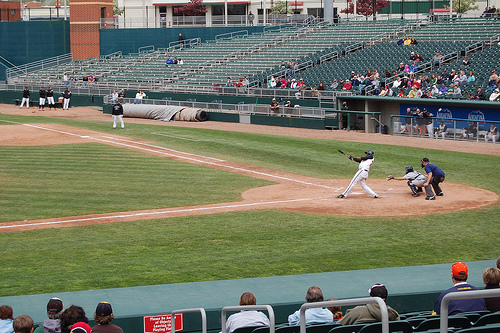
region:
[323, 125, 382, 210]
a man swinging a baseball bat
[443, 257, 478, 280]
a red cap on a head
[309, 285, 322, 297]
a bald spot on a head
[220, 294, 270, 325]
a man wearing a light blue shirt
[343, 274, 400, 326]
a man wearing a gray hoodie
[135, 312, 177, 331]
a red and white safety sign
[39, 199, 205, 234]
a white chalk line in the dirt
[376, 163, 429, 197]
a catcher reaching for the ball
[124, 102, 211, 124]
a long rolls of astro turf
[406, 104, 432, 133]
coaches watching the game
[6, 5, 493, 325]
They are playing baseball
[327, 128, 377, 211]
He is swinging a bat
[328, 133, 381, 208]
He is in the batter's box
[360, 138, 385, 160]
The man is wearing a helmet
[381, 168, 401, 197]
The catcher is holding a glove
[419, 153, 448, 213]
The umpire is crouched over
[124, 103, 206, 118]
A tarp that is rolled up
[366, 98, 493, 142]
Players and coaches in the dugout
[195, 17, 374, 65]
Many empty seats in the stands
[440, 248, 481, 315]
A man wearing an orange hat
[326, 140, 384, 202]
a batter swinging at a baseball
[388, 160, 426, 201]
a baseball catcher catching a ball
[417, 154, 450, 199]
a baseball umpire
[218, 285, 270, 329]
a spectator at a baseball game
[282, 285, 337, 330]
a spectator at a baseball game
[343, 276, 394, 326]
a spectator at a baseball game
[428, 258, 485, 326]
a spectator at a baseball game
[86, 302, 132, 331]
a spectator at a baseball game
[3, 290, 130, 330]
spectators at a baseball game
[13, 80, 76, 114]
several baseball players standing in a row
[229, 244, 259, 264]
Small part of the green grass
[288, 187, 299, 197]
Small part of the brown grass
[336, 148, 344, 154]
Black bat of the batter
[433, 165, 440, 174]
Blue shirt of the umpire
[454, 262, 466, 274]
Orange cap of spectator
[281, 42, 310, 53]
Group of green seats in the sand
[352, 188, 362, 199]
White home plate on baseball field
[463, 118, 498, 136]
Players in the dugout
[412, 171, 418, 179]
Gray shirt of the catcher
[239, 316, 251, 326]
White shirt of the spectator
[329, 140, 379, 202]
baseball player swinging bat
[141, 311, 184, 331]
red and white sign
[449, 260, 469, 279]
bright red ball cap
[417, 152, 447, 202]
umpire squatting behind catcher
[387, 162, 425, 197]
catcher squatting behind hitter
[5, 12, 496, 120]
large stadium in background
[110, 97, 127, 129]
ball player near first base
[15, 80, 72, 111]
four players watching game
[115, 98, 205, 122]
large roll of outdoor carpet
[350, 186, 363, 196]
home plate between player's legs